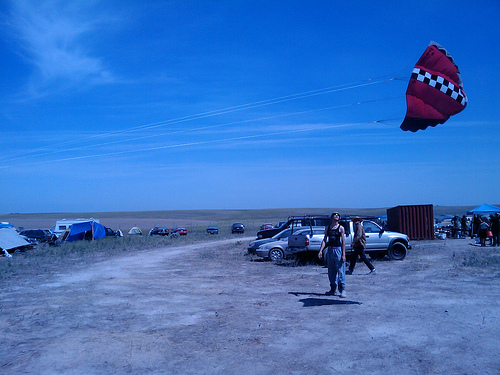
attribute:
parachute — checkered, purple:
[400, 39, 467, 133]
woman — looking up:
[317, 212, 351, 301]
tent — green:
[1, 223, 31, 255]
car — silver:
[254, 232, 294, 263]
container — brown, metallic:
[385, 205, 433, 241]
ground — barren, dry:
[0, 206, 499, 374]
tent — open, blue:
[62, 220, 121, 243]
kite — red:
[399, 41, 465, 130]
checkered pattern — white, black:
[411, 68, 466, 107]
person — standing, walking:
[344, 215, 378, 276]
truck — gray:
[286, 217, 413, 263]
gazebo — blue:
[464, 203, 500, 239]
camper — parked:
[54, 218, 100, 242]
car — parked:
[246, 225, 325, 261]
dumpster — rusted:
[385, 204, 436, 243]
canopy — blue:
[465, 203, 500, 239]